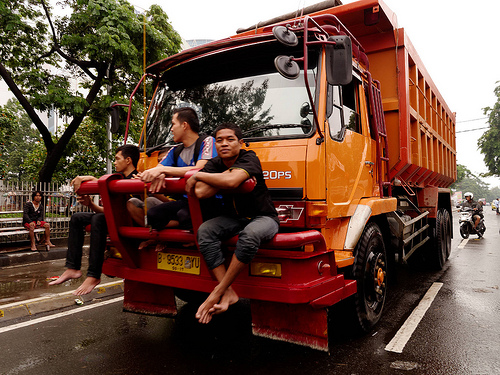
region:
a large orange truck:
[112, 11, 456, 292]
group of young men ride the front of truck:
[60, 113, 289, 315]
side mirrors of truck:
[324, 29, 356, 93]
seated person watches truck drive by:
[21, 188, 56, 261]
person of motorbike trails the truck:
[459, 189, 489, 248]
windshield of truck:
[159, 56, 334, 142]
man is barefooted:
[191, 279, 266, 331]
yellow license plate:
[154, 254, 204, 275]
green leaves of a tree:
[68, 0, 178, 65]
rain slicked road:
[416, 258, 496, 370]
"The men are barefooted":
[22, 225, 255, 329]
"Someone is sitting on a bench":
[16, 173, 65, 257]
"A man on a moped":
[452, 183, 489, 258]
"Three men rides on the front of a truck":
[47, 64, 456, 354]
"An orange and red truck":
[103, 0, 478, 352]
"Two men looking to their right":
[79, 90, 216, 308]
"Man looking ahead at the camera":
[191, 113, 278, 330]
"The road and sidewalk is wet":
[1, 249, 174, 358]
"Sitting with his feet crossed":
[192, 207, 280, 334]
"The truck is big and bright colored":
[50, 2, 468, 352]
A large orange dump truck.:
[70, 15, 463, 340]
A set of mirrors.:
[270, 0, 352, 135]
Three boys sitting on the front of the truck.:
[70, 115, 280, 296]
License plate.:
[145, 245, 200, 280]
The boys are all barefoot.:
[41, 100, 276, 320]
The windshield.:
[140, 37, 327, 137]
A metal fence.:
[0, 175, 96, 240]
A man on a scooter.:
[450, 180, 486, 245]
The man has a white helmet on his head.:
[455, 190, 480, 204]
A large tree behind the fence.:
[0, 0, 175, 176]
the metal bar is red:
[104, 171, 289, 251]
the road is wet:
[466, 267, 481, 342]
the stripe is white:
[401, 282, 440, 373]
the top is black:
[196, 159, 277, 214]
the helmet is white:
[461, 191, 476, 199]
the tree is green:
[33, 80, 74, 108]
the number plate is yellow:
[153, 257, 196, 273]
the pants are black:
[68, 210, 111, 273]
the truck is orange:
[298, 84, 484, 189]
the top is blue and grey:
[162, 146, 218, 200]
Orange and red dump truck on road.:
[98, 8, 498, 362]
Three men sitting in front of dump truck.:
[51, 104, 286, 324]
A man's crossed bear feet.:
[194, 278, 247, 327]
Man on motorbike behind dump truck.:
[451, 187, 491, 247]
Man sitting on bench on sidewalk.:
[13, 189, 50, 256]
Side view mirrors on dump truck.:
[277, 12, 369, 149]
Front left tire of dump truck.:
[341, 225, 395, 339]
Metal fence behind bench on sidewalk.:
[11, 176, 86, 244]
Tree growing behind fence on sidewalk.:
[11, 4, 168, 208]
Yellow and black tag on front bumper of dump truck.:
[150, 246, 208, 278]